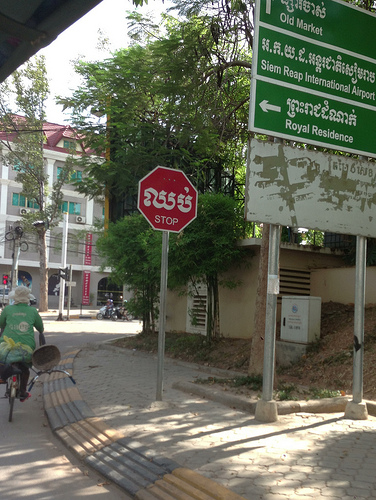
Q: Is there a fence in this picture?
A: No, there are no fences.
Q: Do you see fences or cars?
A: No, there are no fences or cars.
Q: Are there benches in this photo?
A: No, there are no benches.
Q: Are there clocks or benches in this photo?
A: No, there are no benches or clocks.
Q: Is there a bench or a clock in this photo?
A: No, there are no benches or clocks.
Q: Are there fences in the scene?
A: No, there are no fences.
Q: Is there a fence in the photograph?
A: No, there are no fences.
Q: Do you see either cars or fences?
A: No, there are no fences or cars.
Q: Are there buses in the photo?
A: No, there are no buses.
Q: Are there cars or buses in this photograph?
A: No, there are no buses or cars.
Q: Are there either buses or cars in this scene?
A: No, there are no buses or cars.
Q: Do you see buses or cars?
A: No, there are no buses or cars.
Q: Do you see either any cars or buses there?
A: No, there are no buses or cars.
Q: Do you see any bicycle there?
A: Yes, there is a bicycle.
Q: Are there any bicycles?
A: Yes, there is a bicycle.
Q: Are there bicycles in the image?
A: Yes, there is a bicycle.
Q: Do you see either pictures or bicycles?
A: Yes, there is a bicycle.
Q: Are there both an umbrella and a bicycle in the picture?
A: No, there is a bicycle but no umbrellas.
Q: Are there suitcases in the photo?
A: No, there are no suitcases.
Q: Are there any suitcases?
A: No, there are no suitcases.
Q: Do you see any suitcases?
A: No, there are no suitcases.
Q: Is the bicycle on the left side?
A: Yes, the bicycle is on the left of the image.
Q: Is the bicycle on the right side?
A: No, the bicycle is on the left of the image.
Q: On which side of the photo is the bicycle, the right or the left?
A: The bicycle is on the left of the image.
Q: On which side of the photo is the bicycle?
A: The bicycle is on the left of the image.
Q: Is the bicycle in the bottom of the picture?
A: Yes, the bicycle is in the bottom of the image.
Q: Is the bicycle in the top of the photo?
A: No, the bicycle is in the bottom of the image.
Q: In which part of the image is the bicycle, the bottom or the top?
A: The bicycle is in the bottom of the image.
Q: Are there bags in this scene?
A: No, there are no bags.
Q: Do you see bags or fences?
A: No, there are no bags or fences.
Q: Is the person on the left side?
A: Yes, the person is on the left of the image.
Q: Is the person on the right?
A: No, the person is on the left of the image.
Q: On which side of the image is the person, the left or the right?
A: The person is on the left of the image.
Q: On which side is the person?
A: The person is on the left of the image.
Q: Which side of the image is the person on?
A: The person is on the left of the image.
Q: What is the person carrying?
A: The person is carrying a bicycle.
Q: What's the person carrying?
A: The person is carrying a bicycle.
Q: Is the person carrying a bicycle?
A: Yes, the person is carrying a bicycle.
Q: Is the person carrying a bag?
A: No, the person is carrying a bicycle.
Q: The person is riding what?
A: The person is riding the bicycle.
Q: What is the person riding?
A: The person is riding the bicycle.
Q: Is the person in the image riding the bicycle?
A: Yes, the person is riding the bicycle.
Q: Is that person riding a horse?
A: No, the person is riding the bicycle.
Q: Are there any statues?
A: No, there are no statues.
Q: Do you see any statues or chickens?
A: No, there are no statues or chickens.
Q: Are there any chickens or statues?
A: No, there are no statues or chickens.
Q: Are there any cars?
A: No, there are no cars.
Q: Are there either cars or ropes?
A: No, there are no cars or ropes.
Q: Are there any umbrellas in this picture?
A: No, there are no umbrellas.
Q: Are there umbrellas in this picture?
A: No, there are no umbrellas.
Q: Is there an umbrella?
A: No, there are no umbrellas.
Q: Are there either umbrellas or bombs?
A: No, there are no umbrellas or bombs.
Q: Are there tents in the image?
A: No, there are no tents.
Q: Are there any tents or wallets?
A: No, there are no tents or wallets.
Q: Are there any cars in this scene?
A: No, there are no cars.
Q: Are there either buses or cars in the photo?
A: No, there are no cars or buses.